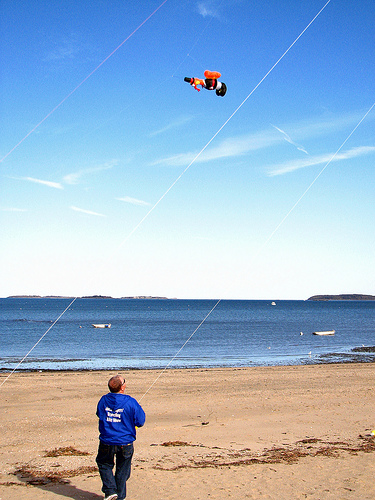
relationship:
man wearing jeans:
[91, 376, 148, 496] [90, 437, 134, 499]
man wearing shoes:
[91, 376, 148, 496] [97, 489, 118, 499]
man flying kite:
[91, 376, 148, 496] [181, 68, 230, 98]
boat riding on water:
[312, 326, 337, 338] [0, 293, 371, 369]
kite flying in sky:
[181, 68, 230, 98] [2, 1, 370, 297]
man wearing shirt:
[91, 376, 148, 496] [94, 391, 147, 444]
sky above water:
[2, 1, 370, 297] [0, 293, 371, 369]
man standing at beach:
[91, 376, 148, 496] [2, 366, 373, 498]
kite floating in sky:
[181, 68, 230, 98] [2, 1, 370, 297]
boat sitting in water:
[312, 326, 337, 338] [0, 293, 371, 369]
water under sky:
[0, 293, 371, 369] [2, 1, 370, 297]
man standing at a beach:
[91, 376, 148, 496] [2, 366, 373, 498]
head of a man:
[106, 374, 129, 396] [91, 376, 148, 496]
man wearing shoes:
[91, 376, 148, 496] [97, 488, 123, 498]